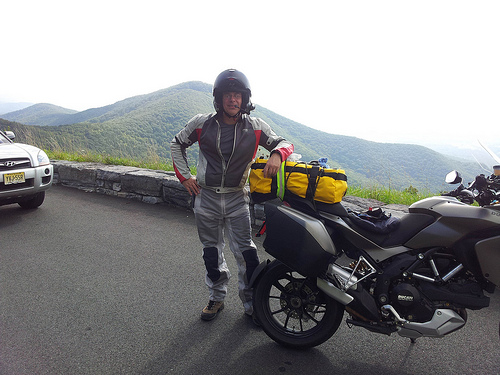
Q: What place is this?
A: It is a road.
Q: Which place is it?
A: It is a road.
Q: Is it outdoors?
A: Yes, it is outdoors.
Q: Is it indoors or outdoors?
A: It is outdoors.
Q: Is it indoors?
A: No, it is outdoors.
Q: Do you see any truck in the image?
A: No, there are no trucks.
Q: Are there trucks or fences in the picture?
A: No, there are no trucks or fences.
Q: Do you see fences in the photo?
A: No, there are no fences.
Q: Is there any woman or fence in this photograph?
A: No, there are no fences or women.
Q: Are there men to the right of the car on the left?
A: Yes, there is a man to the right of the car.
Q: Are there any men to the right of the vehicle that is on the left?
A: Yes, there is a man to the right of the car.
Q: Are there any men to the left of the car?
A: No, the man is to the right of the car.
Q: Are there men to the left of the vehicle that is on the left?
A: No, the man is to the right of the car.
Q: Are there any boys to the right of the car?
A: No, there is a man to the right of the car.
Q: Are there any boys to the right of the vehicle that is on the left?
A: No, there is a man to the right of the car.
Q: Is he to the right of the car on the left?
A: Yes, the man is to the right of the car.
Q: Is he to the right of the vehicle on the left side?
A: Yes, the man is to the right of the car.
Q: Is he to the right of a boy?
A: No, the man is to the right of the car.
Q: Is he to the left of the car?
A: No, the man is to the right of the car.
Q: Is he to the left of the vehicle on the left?
A: No, the man is to the right of the car.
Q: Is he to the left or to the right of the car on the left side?
A: The man is to the right of the car.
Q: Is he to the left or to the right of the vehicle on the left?
A: The man is to the right of the car.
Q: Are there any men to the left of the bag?
A: Yes, there is a man to the left of the bag.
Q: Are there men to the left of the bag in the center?
A: Yes, there is a man to the left of the bag.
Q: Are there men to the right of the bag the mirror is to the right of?
A: No, the man is to the left of the bag.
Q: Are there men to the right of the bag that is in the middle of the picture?
A: No, the man is to the left of the bag.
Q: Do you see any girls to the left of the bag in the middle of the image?
A: No, there is a man to the left of the bag.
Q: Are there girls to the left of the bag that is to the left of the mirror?
A: No, there is a man to the left of the bag.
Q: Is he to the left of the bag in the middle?
A: Yes, the man is to the left of the bag.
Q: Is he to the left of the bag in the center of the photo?
A: Yes, the man is to the left of the bag.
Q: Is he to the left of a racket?
A: No, the man is to the left of the bag.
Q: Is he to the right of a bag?
A: No, the man is to the left of a bag.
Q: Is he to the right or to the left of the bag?
A: The man is to the left of the bag.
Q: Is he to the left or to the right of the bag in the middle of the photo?
A: The man is to the left of the bag.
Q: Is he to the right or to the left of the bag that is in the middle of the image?
A: The man is to the left of the bag.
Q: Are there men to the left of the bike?
A: Yes, there is a man to the left of the bike.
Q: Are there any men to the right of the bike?
A: No, the man is to the left of the bike.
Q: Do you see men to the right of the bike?
A: No, the man is to the left of the bike.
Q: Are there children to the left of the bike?
A: No, there is a man to the left of the bike.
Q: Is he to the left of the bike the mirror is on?
A: Yes, the man is to the left of the bike.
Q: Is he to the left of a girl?
A: No, the man is to the left of the bike.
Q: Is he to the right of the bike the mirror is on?
A: No, the man is to the left of the bike.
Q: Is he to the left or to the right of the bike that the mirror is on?
A: The man is to the left of the bike.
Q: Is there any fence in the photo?
A: No, there are no fences.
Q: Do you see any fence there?
A: No, there are no fences.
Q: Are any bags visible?
A: Yes, there is a bag.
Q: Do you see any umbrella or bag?
A: Yes, there is a bag.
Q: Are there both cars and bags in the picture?
A: Yes, there are both a bag and a car.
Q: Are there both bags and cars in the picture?
A: Yes, there are both a bag and a car.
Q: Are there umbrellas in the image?
A: No, there are no umbrellas.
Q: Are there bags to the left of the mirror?
A: Yes, there is a bag to the left of the mirror.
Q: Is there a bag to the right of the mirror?
A: No, the bag is to the left of the mirror.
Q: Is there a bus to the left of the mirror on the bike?
A: No, there is a bag to the left of the mirror.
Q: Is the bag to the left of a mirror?
A: Yes, the bag is to the left of a mirror.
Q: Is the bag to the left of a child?
A: No, the bag is to the left of a mirror.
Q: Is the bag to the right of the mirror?
A: No, the bag is to the left of the mirror.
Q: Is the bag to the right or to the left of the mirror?
A: The bag is to the left of the mirror.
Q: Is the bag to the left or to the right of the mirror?
A: The bag is to the left of the mirror.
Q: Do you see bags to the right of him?
A: Yes, there is a bag to the right of the man.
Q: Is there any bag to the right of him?
A: Yes, there is a bag to the right of the man.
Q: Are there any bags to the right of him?
A: Yes, there is a bag to the right of the man.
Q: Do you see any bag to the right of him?
A: Yes, there is a bag to the right of the man.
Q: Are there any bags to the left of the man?
A: No, the bag is to the right of the man.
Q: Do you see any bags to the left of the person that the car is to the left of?
A: No, the bag is to the right of the man.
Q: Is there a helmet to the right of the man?
A: No, there is a bag to the right of the man.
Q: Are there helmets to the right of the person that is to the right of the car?
A: No, there is a bag to the right of the man.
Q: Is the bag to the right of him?
A: Yes, the bag is to the right of a man.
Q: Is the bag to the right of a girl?
A: No, the bag is to the right of a man.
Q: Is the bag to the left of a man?
A: No, the bag is to the right of a man.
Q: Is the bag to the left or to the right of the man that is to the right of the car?
A: The bag is to the right of the man.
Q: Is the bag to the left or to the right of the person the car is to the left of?
A: The bag is to the right of the man.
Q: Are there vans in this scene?
A: No, there are no vans.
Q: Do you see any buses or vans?
A: No, there are no vans or buses.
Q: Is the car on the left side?
A: Yes, the car is on the left of the image.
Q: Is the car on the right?
A: No, the car is on the left of the image.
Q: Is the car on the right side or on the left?
A: The car is on the left of the image.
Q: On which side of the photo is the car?
A: The car is on the left of the image.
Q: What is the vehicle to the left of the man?
A: The vehicle is a car.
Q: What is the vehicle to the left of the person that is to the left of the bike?
A: The vehicle is a car.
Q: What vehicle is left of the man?
A: The vehicle is a car.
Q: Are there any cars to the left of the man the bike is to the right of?
A: Yes, there is a car to the left of the man.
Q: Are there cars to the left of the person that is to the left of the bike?
A: Yes, there is a car to the left of the man.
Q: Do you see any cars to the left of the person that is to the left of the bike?
A: Yes, there is a car to the left of the man.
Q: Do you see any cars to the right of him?
A: No, the car is to the left of the man.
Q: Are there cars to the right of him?
A: No, the car is to the left of the man.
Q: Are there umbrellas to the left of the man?
A: No, there is a car to the left of the man.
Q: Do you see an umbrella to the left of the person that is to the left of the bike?
A: No, there is a car to the left of the man.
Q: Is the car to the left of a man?
A: Yes, the car is to the left of a man.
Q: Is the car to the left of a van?
A: No, the car is to the left of a man.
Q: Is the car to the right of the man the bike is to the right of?
A: No, the car is to the left of the man.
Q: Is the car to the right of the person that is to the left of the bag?
A: No, the car is to the left of the man.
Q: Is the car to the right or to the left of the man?
A: The car is to the left of the man.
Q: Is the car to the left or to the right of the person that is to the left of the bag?
A: The car is to the left of the man.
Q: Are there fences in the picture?
A: No, there are no fences.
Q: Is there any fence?
A: No, there are no fences.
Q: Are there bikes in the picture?
A: Yes, there is a bike.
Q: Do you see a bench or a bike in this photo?
A: Yes, there is a bike.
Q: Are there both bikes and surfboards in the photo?
A: No, there is a bike but no surfboards.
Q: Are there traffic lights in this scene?
A: No, there are no traffic lights.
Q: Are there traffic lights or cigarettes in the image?
A: No, there are no traffic lights or cigarettes.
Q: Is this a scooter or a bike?
A: This is a bike.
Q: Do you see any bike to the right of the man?
A: Yes, there is a bike to the right of the man.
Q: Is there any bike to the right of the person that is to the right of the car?
A: Yes, there is a bike to the right of the man.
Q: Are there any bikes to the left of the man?
A: No, the bike is to the right of the man.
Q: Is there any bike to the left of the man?
A: No, the bike is to the right of the man.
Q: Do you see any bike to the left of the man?
A: No, the bike is to the right of the man.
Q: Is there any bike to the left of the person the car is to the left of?
A: No, the bike is to the right of the man.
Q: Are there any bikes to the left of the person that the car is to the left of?
A: No, the bike is to the right of the man.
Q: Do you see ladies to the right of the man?
A: No, there is a bike to the right of the man.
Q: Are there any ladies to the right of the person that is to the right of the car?
A: No, there is a bike to the right of the man.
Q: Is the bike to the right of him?
A: Yes, the bike is to the right of the man.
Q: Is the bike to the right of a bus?
A: No, the bike is to the right of the man.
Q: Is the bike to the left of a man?
A: No, the bike is to the right of a man.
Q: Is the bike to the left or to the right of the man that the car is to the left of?
A: The bike is to the right of the man.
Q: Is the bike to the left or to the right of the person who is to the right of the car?
A: The bike is to the right of the man.